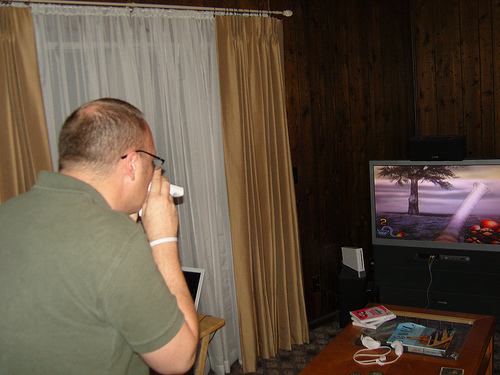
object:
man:
[2, 98, 201, 375]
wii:
[343, 247, 365, 277]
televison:
[369, 160, 497, 253]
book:
[350, 303, 397, 322]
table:
[299, 304, 496, 375]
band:
[146, 237, 183, 248]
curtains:
[214, 16, 310, 373]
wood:
[286, 6, 498, 132]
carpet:
[264, 320, 353, 375]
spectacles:
[153, 158, 165, 170]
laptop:
[181, 266, 207, 315]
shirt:
[0, 172, 187, 375]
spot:
[81, 104, 101, 119]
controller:
[353, 335, 406, 368]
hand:
[140, 168, 180, 238]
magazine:
[388, 321, 459, 357]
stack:
[350, 303, 396, 332]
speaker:
[406, 136, 468, 160]